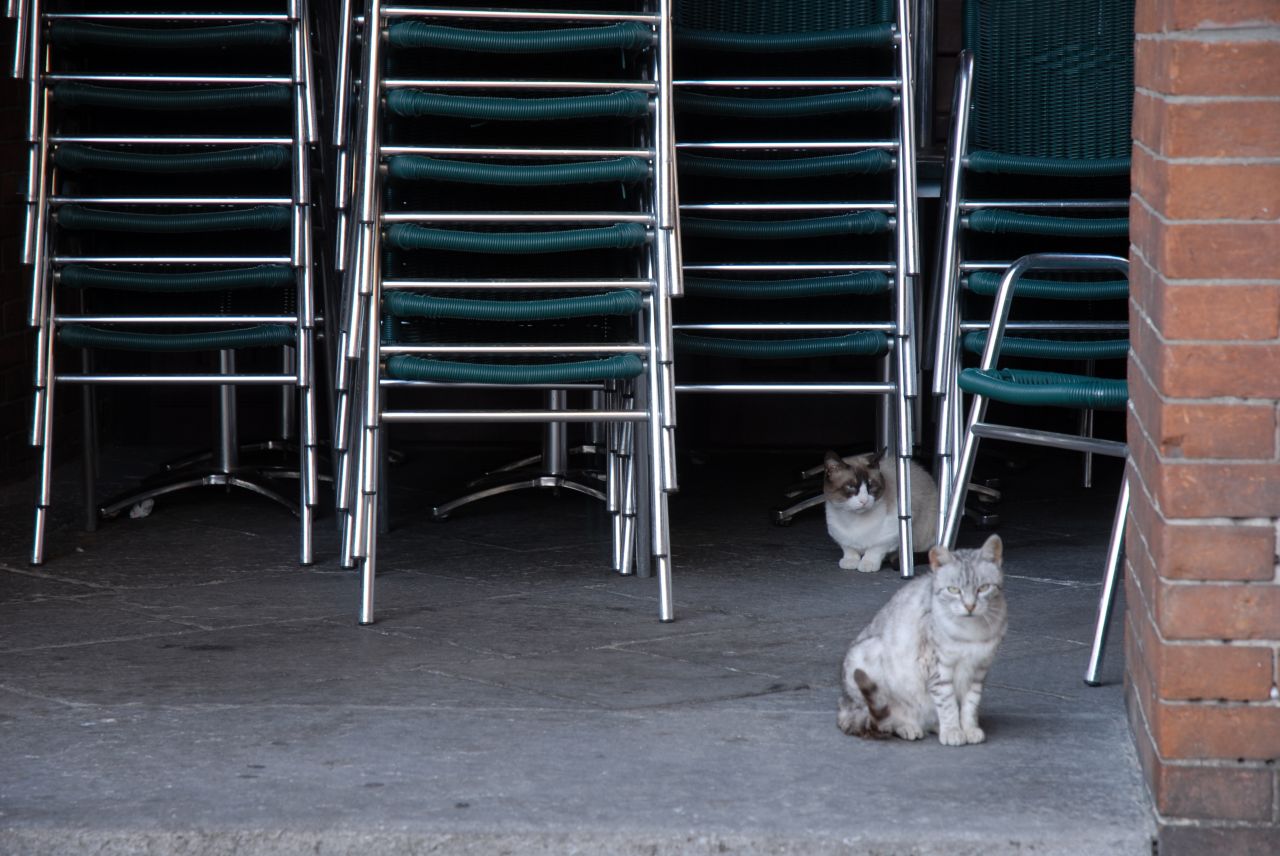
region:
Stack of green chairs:
[9, 0, 319, 577]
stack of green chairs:
[341, 4, 666, 622]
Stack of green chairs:
[676, 2, 908, 587]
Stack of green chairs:
[952, 8, 1129, 520]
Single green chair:
[943, 249, 1125, 687]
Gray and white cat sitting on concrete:
[850, 551, 999, 746]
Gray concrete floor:
[10, 468, 1132, 853]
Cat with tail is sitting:
[842, 534, 1008, 740]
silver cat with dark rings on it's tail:
[847, 534, 1028, 751]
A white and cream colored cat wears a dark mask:
[781, 437, 943, 575]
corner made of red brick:
[1137, 14, 1275, 851]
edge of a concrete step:
[12, 773, 1164, 853]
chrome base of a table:
[99, 362, 320, 546]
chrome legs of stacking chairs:
[644, 51, 689, 628]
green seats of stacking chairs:
[392, 203, 644, 407]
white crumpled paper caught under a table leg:
[123, 483, 170, 530]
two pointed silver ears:
[917, 528, 1013, 575]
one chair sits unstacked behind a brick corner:
[891, 236, 1159, 715]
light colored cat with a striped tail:
[837, 526, 1007, 743]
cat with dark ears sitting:
[822, 442, 937, 571]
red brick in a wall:
[1153, 512, 1275, 583]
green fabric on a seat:
[389, 84, 646, 124]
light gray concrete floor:
[6, 433, 1159, 851]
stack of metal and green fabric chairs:
[343, 9, 684, 621]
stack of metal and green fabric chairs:
[6, 5, 329, 571]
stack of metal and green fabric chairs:
[643, 9, 931, 577]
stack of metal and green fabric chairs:
[930, 9, 1134, 566]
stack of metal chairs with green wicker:
[11, 6, 332, 600]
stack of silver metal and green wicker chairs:
[327, 6, 683, 638]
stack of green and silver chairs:
[675, 15, 927, 583]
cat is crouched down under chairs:
[817, 445, 954, 583]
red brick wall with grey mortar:
[1119, 6, 1272, 852]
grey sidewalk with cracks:
[11, 500, 1153, 852]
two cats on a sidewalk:
[788, 429, 1025, 765]